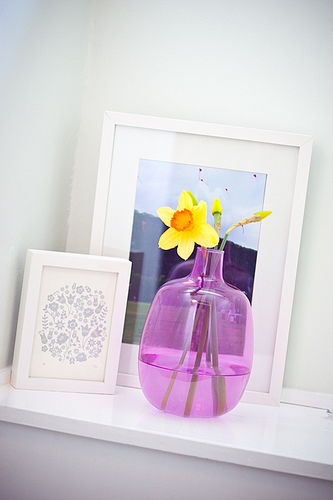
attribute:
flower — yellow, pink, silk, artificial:
[152, 191, 220, 260]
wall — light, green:
[11, 8, 317, 112]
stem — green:
[220, 231, 226, 249]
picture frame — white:
[9, 248, 131, 395]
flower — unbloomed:
[210, 197, 221, 217]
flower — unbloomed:
[225, 209, 272, 233]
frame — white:
[86, 109, 314, 407]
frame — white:
[9, 250, 36, 387]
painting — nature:
[130, 153, 282, 295]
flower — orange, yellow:
[168, 208, 195, 232]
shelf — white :
[0, 363, 333, 498]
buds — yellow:
[209, 196, 274, 224]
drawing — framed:
[38, 284, 108, 363]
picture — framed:
[28, 262, 118, 386]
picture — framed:
[101, 124, 295, 409]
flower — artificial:
[156, 193, 269, 417]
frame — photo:
[100, 111, 257, 333]